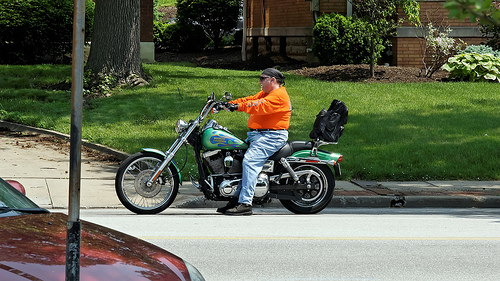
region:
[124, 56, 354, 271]
the man is riding motorcycle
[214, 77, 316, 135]
the jacket is orange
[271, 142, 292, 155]
the seat is leather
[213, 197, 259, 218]
the shoes are black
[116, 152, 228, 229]
the tire is black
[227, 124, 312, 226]
the pants is jean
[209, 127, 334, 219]
the jeans are blue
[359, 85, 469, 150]
the grass is green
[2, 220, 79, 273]
the car is parked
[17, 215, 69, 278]
the car is red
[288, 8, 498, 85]
Landscaping near a house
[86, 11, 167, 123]
A tree trunk on a lawn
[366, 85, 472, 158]
A segment of lawn in sunlight and shadow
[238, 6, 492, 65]
A building with a brick exterior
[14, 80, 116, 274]
A pole in front of a car hood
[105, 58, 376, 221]
A man on a motorcycle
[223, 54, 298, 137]
A man in an orange shirt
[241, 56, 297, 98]
A man wearing sunglasses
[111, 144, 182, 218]
Front wheel of a motorcycle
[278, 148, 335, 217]
Back wheel of a motorcycle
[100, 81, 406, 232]
Man on a motorcycle.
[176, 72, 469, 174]
Grass behind motorcycle.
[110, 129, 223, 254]
Front wheel of the motorcycle.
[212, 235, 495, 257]
Yellow line on road.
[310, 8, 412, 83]
Green bush against house.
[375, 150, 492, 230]
Sidewalk by the grass.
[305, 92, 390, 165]
Black bag on motorcycle.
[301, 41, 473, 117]
Brown dirt under bush.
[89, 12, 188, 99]
Tree in the background.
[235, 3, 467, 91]
Building on the grass.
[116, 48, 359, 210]
man sitting on motorcycle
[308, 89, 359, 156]
backpack on motorcycle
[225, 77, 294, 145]
long sleeved orange shirt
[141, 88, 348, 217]
green motorcycle with blue flames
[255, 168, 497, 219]
sidewalk along side of street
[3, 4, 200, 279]
car sitting beside pole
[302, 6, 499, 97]
bushes beside brick building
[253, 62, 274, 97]
man wearing sunglasses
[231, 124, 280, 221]
man wearing denim pants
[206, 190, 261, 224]
man wearing black boots